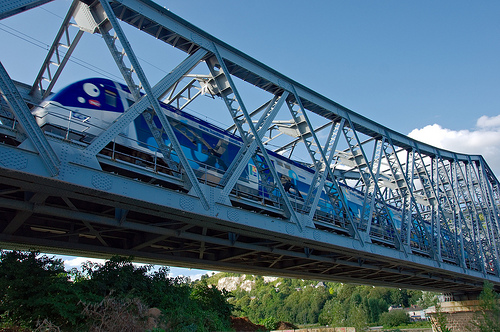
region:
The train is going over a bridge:
[8, 20, 488, 308]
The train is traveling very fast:
[10, 30, 492, 317]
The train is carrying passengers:
[17, 18, 493, 311]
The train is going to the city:
[5, 15, 491, 306]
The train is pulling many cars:
[3, 32, 488, 302]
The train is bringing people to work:
[2, 5, 490, 300]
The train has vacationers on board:
[6, 31, 492, 296]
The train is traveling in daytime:
[8, 26, 494, 301]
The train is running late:
[12, 40, 489, 305]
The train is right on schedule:
[8, 35, 494, 302]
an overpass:
[307, 115, 452, 227]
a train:
[54, 73, 159, 137]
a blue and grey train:
[50, 74, 117, 131]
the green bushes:
[129, 271, 199, 305]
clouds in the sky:
[429, 118, 478, 147]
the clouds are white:
[417, 121, 469, 149]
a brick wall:
[430, 298, 469, 325]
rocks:
[215, 272, 270, 294]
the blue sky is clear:
[369, 85, 424, 116]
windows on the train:
[190, 123, 228, 157]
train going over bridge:
[62, 3, 495, 292]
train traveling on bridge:
[26, 0, 489, 272]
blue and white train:
[51, 57, 371, 217]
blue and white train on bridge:
[37, 15, 499, 292]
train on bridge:
[51, 0, 493, 285]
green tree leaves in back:
[256, 284, 346, 324]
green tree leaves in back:
[117, 260, 229, 330]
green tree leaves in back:
[6, 251, 83, 323]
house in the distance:
[400, 295, 438, 322]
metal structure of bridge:
[203, 20, 494, 276]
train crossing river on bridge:
[2, 1, 499, 328]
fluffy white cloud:
[339, 115, 499, 203]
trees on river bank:
[2, 252, 444, 330]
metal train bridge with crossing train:
[3, 1, 494, 288]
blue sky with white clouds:
[2, 0, 494, 196]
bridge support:
[421, 288, 492, 328]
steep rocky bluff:
[206, 272, 279, 289]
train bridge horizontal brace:
[170, 71, 213, 107]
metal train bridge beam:
[105, 0, 355, 122]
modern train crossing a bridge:
[8, 5, 493, 329]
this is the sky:
[366, 1, 454, 53]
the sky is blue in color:
[337, 18, 408, 54]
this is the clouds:
[423, 122, 495, 157]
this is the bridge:
[106, 116, 433, 296]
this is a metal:
[290, 107, 359, 215]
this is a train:
[53, 84, 110, 114]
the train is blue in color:
[203, 132, 232, 147]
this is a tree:
[161, 277, 223, 322]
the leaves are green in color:
[172, 283, 192, 305]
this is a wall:
[438, 300, 476, 330]